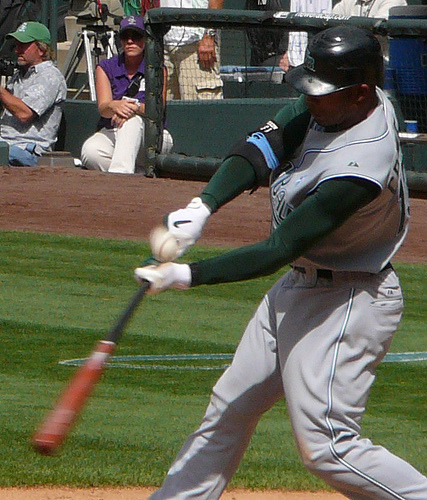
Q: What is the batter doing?
A: Swinging a bat.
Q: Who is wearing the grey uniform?
A: The batter.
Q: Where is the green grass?
A: On the field.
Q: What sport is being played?
A: Baseball.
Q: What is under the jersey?
A: Green undershirt.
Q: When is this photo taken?
A: During a baseball game.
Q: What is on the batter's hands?
A: White batting gloves.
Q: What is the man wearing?
A: White batting gloves.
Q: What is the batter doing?
A: Hitting a ball.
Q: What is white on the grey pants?
A: Stripe on player's left leg.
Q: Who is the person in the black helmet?
A: Player swinging against stiff front leg.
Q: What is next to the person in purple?
A: Padded railing near baseball field.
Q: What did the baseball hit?
A: Left arm of batter.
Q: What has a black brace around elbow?
A: Right arm of batter.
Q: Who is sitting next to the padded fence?
A: A woman in white pants, a purple shirt and purple cap watching the game.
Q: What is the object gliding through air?
A: The player's red and black baseball bat.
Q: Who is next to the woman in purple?
A: A man wearing a grey shirt and green cap.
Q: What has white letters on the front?
A: The baseball player's black helmet.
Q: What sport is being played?
A: Baseball.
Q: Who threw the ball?
A: The pitcher.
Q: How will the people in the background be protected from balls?
A: The fence.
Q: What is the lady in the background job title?
A: A reporter.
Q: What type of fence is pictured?
A: Wire.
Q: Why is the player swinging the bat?
A: To hit the ball.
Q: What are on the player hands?
A: Gloves.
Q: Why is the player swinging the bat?
A: Trying to hit the ball.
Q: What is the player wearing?
A: Uniform.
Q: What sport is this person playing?
A: Baseball.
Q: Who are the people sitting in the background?
A: Spectators.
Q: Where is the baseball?
A: Between the batter's hands.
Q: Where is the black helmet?
A: Batter's head.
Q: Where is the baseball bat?
A: Held in batter's hands.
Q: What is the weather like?
A: Sunny.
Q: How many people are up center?
A: One.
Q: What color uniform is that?
A: Gray.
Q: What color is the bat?
A: Red and black.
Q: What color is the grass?
A: Green.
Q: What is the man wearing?
A: Helmet.